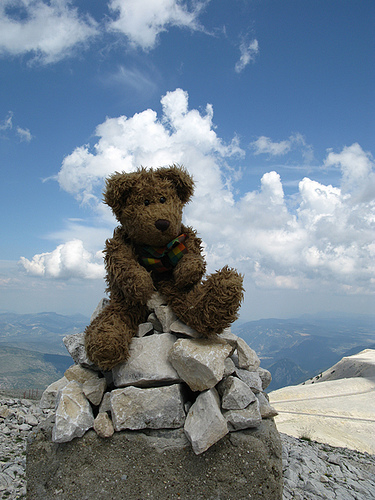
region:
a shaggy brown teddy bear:
[68, 167, 253, 341]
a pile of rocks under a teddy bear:
[45, 289, 276, 455]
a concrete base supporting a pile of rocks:
[20, 409, 267, 495]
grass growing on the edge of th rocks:
[287, 423, 312, 439]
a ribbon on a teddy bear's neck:
[124, 227, 191, 269]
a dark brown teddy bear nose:
[151, 215, 169, 230]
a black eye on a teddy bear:
[142, 196, 148, 203]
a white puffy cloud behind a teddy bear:
[62, 84, 246, 285]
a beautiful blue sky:
[2, 3, 371, 309]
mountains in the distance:
[241, 313, 356, 358]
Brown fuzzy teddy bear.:
[78, 162, 246, 370]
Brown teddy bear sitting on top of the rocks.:
[49, 161, 275, 435]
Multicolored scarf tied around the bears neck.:
[132, 231, 192, 269]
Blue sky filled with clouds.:
[3, 3, 361, 163]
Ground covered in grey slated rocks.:
[280, 425, 372, 495]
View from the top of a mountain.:
[5, 114, 329, 411]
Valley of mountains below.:
[268, 304, 373, 382]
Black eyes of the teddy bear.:
[138, 194, 172, 208]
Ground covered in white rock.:
[276, 379, 372, 435]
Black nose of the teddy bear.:
[145, 213, 176, 234]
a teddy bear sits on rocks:
[72, 155, 255, 386]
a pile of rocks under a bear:
[31, 290, 288, 455]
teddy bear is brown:
[64, 152, 257, 368]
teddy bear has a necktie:
[120, 231, 196, 285]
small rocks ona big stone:
[9, 303, 291, 498]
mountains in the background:
[248, 304, 366, 358]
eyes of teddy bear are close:
[131, 188, 172, 211]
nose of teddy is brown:
[145, 213, 175, 236]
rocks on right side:
[276, 437, 372, 499]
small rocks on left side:
[4, 396, 37, 498]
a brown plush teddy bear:
[83, 161, 244, 373]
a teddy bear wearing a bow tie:
[77, 163, 244, 373]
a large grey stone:
[24, 415, 285, 498]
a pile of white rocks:
[32, 298, 278, 448]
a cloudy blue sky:
[3, 0, 368, 320]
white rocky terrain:
[274, 433, 374, 494]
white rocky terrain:
[1, 392, 43, 498]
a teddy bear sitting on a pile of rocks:
[28, 160, 283, 494]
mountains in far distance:
[1, 306, 86, 349]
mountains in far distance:
[234, 314, 374, 370]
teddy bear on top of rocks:
[60, 158, 273, 371]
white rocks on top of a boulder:
[51, 335, 263, 427]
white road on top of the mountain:
[283, 338, 359, 479]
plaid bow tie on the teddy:
[136, 233, 189, 272]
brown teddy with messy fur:
[67, 160, 252, 323]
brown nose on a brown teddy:
[148, 209, 175, 234]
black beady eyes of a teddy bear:
[133, 188, 181, 207]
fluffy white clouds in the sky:
[243, 152, 326, 242]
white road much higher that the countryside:
[256, 291, 370, 398]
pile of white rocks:
[120, 356, 232, 445]